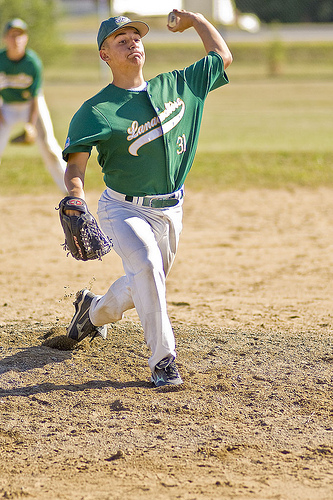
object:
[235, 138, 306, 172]
grass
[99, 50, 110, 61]
ear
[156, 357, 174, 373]
lace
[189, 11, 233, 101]
arm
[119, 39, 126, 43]
eye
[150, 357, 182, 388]
feet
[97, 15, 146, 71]
head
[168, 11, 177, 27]
ball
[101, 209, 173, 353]
leg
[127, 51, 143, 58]
mouth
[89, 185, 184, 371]
pants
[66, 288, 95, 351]
foot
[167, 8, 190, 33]
hand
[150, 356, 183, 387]
shoe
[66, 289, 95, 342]
shoe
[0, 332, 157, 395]
shadow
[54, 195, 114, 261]
glove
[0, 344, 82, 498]
dirt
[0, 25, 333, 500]
ground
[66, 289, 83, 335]
cleats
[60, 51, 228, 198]
jersey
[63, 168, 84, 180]
elbow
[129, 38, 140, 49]
nose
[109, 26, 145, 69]
face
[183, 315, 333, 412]
dirt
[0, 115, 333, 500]
field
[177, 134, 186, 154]
thirtyone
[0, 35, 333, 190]
outfield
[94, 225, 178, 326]
leg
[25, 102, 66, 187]
leg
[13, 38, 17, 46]
nose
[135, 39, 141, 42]
eye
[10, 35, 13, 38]
eye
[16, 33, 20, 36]
eye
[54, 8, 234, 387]
man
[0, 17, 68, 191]
man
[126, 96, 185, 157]
name